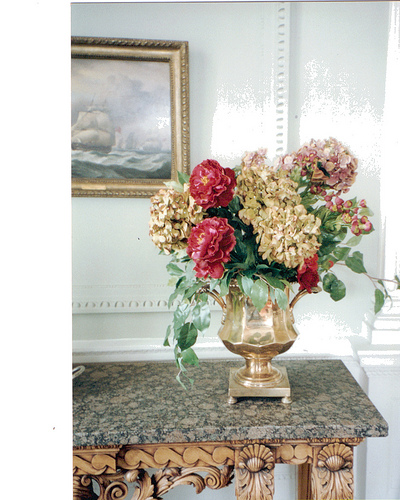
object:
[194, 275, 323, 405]
vase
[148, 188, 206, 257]
flowers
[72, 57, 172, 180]
picture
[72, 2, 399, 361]
wall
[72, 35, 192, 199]
frame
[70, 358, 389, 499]
table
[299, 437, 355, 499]
legs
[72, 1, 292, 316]
moulding